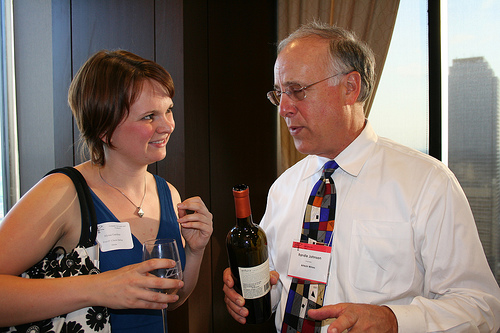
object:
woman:
[3, 40, 215, 332]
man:
[222, 21, 490, 332]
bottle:
[222, 186, 274, 332]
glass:
[140, 238, 184, 331]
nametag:
[286, 248, 331, 287]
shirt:
[246, 128, 488, 332]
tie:
[286, 165, 341, 332]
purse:
[11, 161, 111, 332]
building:
[441, 52, 499, 283]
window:
[274, 6, 499, 294]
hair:
[66, 53, 176, 164]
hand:
[89, 257, 185, 316]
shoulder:
[39, 170, 105, 226]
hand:
[222, 268, 274, 323]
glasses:
[267, 66, 352, 106]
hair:
[273, 25, 383, 99]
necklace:
[99, 170, 150, 219]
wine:
[225, 184, 279, 332]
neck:
[232, 184, 253, 219]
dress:
[82, 170, 184, 332]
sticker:
[92, 221, 134, 251]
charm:
[137, 208, 145, 218]